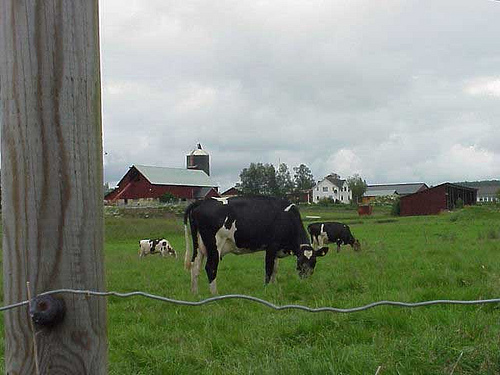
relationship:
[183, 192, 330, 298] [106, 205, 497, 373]
cow eats grass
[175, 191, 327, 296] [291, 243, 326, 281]
cow has head